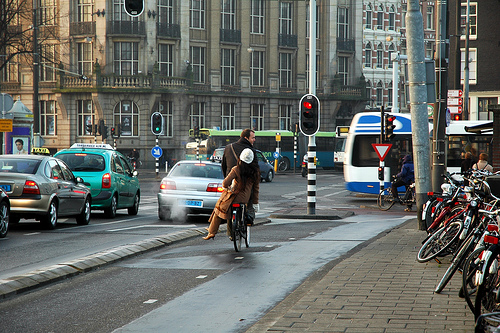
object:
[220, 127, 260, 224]
man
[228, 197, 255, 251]
bike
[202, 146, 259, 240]
woman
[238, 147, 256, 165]
hat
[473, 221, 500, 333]
bicycles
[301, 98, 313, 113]
light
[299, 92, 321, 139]
stoplight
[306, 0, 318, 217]
pole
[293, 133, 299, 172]
pole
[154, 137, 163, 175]
pole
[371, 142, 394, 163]
sign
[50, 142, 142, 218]
taxi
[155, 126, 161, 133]
light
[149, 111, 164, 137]
stoplight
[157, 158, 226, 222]
car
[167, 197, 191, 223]
smoke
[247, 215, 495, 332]
sidewalk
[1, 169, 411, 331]
street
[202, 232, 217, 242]
shoe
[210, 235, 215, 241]
heel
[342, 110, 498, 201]
bus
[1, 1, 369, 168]
building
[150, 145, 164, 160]
sign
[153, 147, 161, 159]
arrow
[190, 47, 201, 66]
window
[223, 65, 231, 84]
window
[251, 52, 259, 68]
window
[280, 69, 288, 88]
window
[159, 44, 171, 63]
window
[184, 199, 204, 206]
license plate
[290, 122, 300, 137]
stoplight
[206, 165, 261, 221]
coat